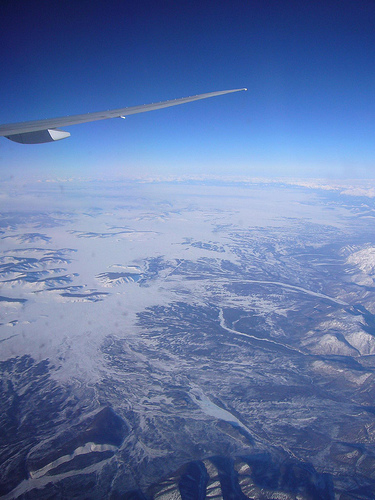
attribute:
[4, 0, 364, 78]
sky — blue 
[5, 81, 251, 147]
wing — white, airplane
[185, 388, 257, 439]
water valley — rocky 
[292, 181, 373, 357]
mountains — brown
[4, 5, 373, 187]
sky — clear, blue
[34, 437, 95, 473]
bag — black 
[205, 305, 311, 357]
river — blue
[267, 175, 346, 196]
clouds — distant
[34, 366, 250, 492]
valley — rocky 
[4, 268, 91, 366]
valley — rocky 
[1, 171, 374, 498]
range — mountain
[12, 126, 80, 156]
bag — silver, black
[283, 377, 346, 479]
water — rocky 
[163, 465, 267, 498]
bag — black 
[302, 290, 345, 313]
bag — silver, black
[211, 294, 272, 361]
water — rocky 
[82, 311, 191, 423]
rocky valley — rocky 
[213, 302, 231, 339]
river — frozen